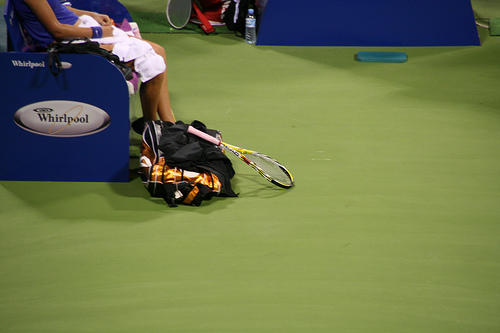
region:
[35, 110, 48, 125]
The letter is black.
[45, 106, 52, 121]
The letter is black.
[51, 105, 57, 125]
The letter is black.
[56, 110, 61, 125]
The letter is black.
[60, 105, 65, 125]
The letter is black.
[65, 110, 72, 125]
The letter is black.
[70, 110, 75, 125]
The letter is black.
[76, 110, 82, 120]
The letter is black.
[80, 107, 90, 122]
The letter is black.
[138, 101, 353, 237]
The tennis racket is on the floor.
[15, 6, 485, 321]
A person is at a tennis court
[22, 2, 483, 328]
A person has just played a game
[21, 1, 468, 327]
A person is resting after playing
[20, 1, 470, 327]
A person is watching a tennis game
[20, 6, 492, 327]
A person has their gear beside them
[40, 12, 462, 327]
A tennis racket is on the floor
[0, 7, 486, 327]
A person is sitting on a bench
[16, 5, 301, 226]
A person is relaxing after a game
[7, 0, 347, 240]
A person is enjoying their day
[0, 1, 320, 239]
A person is having some recreation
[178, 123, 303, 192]
pink handled tennis racket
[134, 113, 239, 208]
yellow and black bag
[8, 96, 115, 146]
whirlpool ad on bench end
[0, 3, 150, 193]
blue bench for seating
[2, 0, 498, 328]
green low nap carpeting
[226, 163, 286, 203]
shadow of racket on floor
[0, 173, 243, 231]
shadow of bag on floor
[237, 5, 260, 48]
water bottle on floor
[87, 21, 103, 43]
blue nike wrist band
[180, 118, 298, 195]
tennis racket leaning on bag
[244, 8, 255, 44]
water bottle with a blue lid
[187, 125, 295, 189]
tennis racket with a pink handle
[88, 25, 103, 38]
blue wristband with a white symbol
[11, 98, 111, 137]
Whirlpool symbol on a blue bench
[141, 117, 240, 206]
a black bag under a tennis racket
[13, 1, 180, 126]
a person on a blue bench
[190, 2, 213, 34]
red strap on the ground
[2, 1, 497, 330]
green floor with blue benches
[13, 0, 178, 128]
person wearing a blue shirt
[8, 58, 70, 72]
Whirlpool on the side of a bench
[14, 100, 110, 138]
whirlpool sponsoring tennis people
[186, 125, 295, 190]
pink and black tennis racquet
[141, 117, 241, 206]
bag for tennis balls and other equipment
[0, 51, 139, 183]
bench for people to sit on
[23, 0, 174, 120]
person sitting on bench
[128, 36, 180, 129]
person sitting with legs crossed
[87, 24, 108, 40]
nike armband for sweat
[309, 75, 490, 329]
green smoothie ground to play on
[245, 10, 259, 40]
water bottle for thirsty people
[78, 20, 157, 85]
towel for wiping sweat